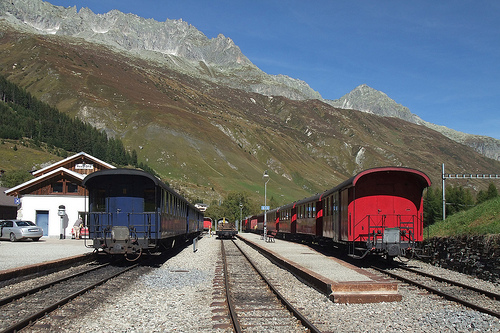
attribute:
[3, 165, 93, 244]
building — brown, white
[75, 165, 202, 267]
passenger train — blue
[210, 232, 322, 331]
tracks — rusty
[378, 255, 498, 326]
tracks — pair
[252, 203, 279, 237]
train car — red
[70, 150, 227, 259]
train — blue, paint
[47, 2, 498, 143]
sky — blue, clear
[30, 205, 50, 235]
door — blue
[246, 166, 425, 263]
train — red, back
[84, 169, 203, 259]
train — blue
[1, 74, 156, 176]
trees — pine, green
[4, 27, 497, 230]
slope — dark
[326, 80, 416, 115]
mountaintop — grey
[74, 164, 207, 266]
train — blue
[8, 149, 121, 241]
building — brown, white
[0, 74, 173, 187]
trees — dense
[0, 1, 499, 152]
mountains — grey, jagged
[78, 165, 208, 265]
blue train — long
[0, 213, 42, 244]
car — silver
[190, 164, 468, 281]
train — red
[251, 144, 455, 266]
train — paint, red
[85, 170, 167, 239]
caboose train — blue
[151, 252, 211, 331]
gravel — rock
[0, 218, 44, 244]
car — silver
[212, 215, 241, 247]
train — third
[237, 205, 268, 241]
passenger car — red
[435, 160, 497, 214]
structure — elevated 